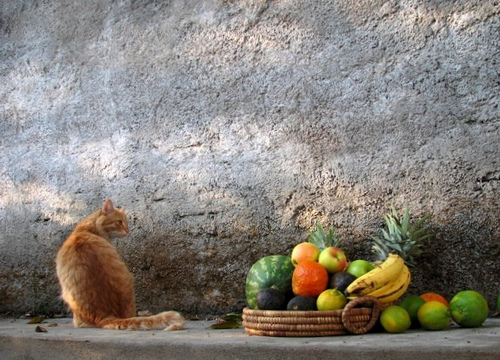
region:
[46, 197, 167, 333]
a yellow striped cat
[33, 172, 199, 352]
a yellow cat sitting on cement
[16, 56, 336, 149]
the wall is gray cement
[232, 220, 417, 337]
a large basket of fruit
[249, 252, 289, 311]
the watermelon is green and striped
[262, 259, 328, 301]
An orange next to a watermelon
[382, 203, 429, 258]
the leaves of a pineapple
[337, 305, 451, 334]
Limes next a basket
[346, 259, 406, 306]
A bunch of bananas and a green apple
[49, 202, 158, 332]
the cat is yellow and striped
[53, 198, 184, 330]
The cat is orange and white.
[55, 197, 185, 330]
The cat is sitting.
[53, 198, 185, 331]
The cat has short fur.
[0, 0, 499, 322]
The wall is made of rock.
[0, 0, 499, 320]
The rock is gray.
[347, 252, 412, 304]
The banana is yellow.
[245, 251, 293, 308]
A watermelon is in the picture.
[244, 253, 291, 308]
The watermelon is green.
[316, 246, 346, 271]
An apple.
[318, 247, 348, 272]
The apple is green and red.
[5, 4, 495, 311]
an exterior wall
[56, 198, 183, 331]
an orange striped cat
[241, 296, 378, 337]
a wide woven basket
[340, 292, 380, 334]
circular handle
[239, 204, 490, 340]
fruit piled on top of and next to basket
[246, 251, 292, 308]
a watermelon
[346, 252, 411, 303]
bananas that are beginning to turn black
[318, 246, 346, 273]
a green and red apple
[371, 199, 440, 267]
the top of a pineapple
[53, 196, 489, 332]
cat looking back at fruit over its shoulder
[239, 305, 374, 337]
brown woven basket holding fruits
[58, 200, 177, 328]
orange cat facing basket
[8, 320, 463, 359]
concrete ledge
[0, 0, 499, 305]
grey stone wall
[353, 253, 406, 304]
bunch of yellow bananas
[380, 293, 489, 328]
green fruit laying next to basket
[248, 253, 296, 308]
green watermelon in basket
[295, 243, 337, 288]
red apples in basket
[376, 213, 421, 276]
pineapple behind bunch of bananas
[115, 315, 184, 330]
cat tail on concrete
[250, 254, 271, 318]
watermelon in the basket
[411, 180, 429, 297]
pineapple against the wall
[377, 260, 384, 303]
bananas next to the pineapple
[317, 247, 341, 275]
apple on top of fruit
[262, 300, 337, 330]
basket holding the fruit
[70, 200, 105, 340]
cat is looking at the fruit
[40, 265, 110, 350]
cat is sitting on the sidewalk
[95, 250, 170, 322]
cat is orange tanish color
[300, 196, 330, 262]
pineapple behind the fruit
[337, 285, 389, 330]
handle on the side of basket